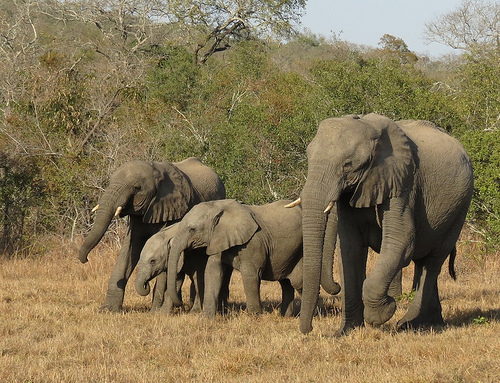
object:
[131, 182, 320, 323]
babies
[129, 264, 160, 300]
trunk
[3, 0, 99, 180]
trees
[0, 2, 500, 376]
savanna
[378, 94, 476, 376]
right side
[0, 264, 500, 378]
field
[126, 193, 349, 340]
elephant walking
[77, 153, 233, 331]
grey elephant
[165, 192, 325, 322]
an elephant walking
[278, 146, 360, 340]
elephant trunk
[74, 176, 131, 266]
long elephant trunk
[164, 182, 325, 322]
wrinkly elephant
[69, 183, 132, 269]
grey wrinkly trunk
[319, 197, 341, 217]
small tusk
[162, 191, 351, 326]
baby elephant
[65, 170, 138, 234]
huge tusks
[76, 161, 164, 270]
head raised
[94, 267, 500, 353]
shadows on ground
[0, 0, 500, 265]
large forest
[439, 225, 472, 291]
short tail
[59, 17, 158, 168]
dead branches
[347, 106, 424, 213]
ear of an elephant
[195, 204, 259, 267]
ear of an elephant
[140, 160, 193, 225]
an ear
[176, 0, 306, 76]
branches of a tree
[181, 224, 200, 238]
eye of an elephant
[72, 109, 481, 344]
four elephants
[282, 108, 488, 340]
big elephant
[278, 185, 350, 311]
two tusks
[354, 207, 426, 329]
leg of elephant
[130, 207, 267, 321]
baby elephant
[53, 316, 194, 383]
dry grass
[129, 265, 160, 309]
trunk is fold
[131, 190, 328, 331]
elephant in middle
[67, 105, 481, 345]
herd of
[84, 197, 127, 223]
white elephant tusks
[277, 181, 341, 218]
two white tusks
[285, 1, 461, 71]
gray sky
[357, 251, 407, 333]
foot lifted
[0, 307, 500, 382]
light brown grass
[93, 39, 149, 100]
tree without leaves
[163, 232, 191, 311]
gray elephant trunk